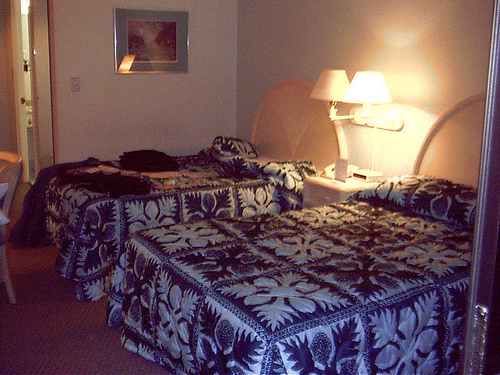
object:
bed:
[102, 174, 489, 373]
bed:
[7, 134, 319, 301]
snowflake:
[215, 269, 352, 332]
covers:
[137, 221, 430, 336]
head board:
[415, 92, 481, 182]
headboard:
[252, 81, 346, 168]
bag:
[115, 149, 179, 172]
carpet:
[1, 181, 193, 374]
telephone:
[333, 158, 348, 182]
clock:
[353, 170, 382, 181]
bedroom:
[0, 0, 499, 373]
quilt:
[105, 199, 476, 375]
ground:
[330, 83, 370, 125]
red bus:
[301, 150, 387, 206]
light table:
[347, 105, 402, 132]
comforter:
[7, 135, 490, 374]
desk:
[298, 163, 387, 209]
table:
[300, 165, 385, 209]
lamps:
[308, 68, 395, 182]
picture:
[115, 6, 191, 76]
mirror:
[29, 0, 56, 185]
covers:
[41, 134, 317, 306]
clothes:
[8, 157, 119, 248]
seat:
[0, 150, 27, 304]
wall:
[0, 0, 488, 191]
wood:
[446, 115, 492, 155]